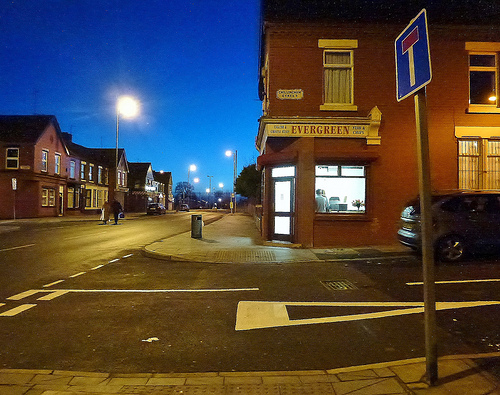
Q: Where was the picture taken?
A: It was taken at the street.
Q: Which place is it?
A: It is a street.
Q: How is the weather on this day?
A: It is clear.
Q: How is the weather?
A: It is clear.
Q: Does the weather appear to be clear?
A: Yes, it is clear.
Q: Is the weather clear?
A: Yes, it is clear.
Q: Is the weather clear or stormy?
A: It is clear.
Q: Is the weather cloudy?
A: No, it is clear.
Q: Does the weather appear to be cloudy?
A: No, it is clear.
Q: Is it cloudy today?
A: No, it is clear.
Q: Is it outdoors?
A: Yes, it is outdoors.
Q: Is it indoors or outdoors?
A: It is outdoors.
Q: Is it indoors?
A: No, it is outdoors.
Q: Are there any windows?
A: Yes, there is a window.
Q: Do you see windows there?
A: Yes, there is a window.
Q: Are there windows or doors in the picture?
A: Yes, there is a window.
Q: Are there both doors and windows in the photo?
A: Yes, there are both a window and a door.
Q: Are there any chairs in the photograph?
A: No, there are no chairs.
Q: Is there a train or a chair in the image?
A: No, there are no chairs or trains.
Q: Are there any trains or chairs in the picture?
A: No, there are no chairs or trains.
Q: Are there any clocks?
A: No, there are no clocks.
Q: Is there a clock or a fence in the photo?
A: No, there are no clocks or fences.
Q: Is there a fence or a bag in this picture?
A: No, there are no fences or bags.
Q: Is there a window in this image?
A: Yes, there is a window.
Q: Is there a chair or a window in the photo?
A: Yes, there is a window.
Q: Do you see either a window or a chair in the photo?
A: Yes, there is a window.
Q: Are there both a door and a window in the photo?
A: Yes, there are both a window and a door.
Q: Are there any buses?
A: No, there are no buses.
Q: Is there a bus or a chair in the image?
A: No, there are no buses or chairs.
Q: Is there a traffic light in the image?
A: No, there are no traffic lights.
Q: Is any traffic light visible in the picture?
A: No, there are no traffic lights.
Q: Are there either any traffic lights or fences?
A: No, there are no traffic lights or fences.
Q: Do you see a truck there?
A: No, there are no trucks.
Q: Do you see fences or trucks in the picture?
A: No, there are no trucks or fences.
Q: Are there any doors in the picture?
A: Yes, there is a door.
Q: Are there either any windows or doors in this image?
A: Yes, there is a door.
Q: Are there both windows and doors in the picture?
A: Yes, there are both a door and windows.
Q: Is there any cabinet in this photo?
A: No, there are no cabinets.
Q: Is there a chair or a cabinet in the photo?
A: No, there are no cabinets or chairs.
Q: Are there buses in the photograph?
A: No, there are no buses.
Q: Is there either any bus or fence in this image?
A: No, there are no buses or fences.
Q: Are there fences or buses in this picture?
A: No, there are no buses or fences.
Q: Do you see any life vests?
A: No, there are no life vests.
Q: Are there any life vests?
A: No, there are no life vests.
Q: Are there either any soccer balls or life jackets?
A: No, there are no life jackets or soccer balls.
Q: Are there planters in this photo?
A: No, there are no planters.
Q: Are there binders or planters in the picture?
A: No, there are no planters or binders.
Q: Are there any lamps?
A: Yes, there is a lamp.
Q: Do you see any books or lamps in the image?
A: Yes, there is a lamp.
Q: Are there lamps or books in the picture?
A: Yes, there is a lamp.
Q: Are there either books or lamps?
A: Yes, there is a lamp.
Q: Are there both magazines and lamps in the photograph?
A: No, there is a lamp but no magazines.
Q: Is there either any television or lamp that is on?
A: Yes, the lamp is on.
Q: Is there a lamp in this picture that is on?
A: Yes, there is a lamp that is on.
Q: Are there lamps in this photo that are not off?
A: Yes, there is a lamp that is on.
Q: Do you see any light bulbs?
A: No, there are no light bulbs.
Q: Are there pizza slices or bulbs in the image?
A: No, there are no bulbs or pizza slices.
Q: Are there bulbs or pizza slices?
A: No, there are no bulbs or pizza slices.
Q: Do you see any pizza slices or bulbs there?
A: No, there are no bulbs or pizza slices.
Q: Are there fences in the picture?
A: No, there are no fences.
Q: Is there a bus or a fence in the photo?
A: No, there are no fences or buses.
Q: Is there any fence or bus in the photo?
A: No, there are no fences or buses.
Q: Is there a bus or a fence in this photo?
A: No, there are no fences or buses.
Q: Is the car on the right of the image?
A: Yes, the car is on the right of the image.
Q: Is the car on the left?
A: No, the car is on the right of the image.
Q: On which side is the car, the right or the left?
A: The car is on the right of the image.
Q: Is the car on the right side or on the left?
A: The car is on the right of the image.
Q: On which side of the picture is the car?
A: The car is on the right of the image.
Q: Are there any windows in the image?
A: Yes, there is a window.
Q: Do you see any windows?
A: Yes, there is a window.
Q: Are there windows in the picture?
A: Yes, there is a window.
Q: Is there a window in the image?
A: Yes, there is a window.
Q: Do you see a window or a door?
A: Yes, there is a window.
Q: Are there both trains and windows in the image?
A: No, there is a window but no trains.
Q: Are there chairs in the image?
A: No, there are no chairs.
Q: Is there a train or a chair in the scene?
A: No, there are no chairs or trains.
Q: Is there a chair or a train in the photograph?
A: No, there are no chairs or trains.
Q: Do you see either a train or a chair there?
A: No, there are no chairs or trains.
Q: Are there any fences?
A: No, there are no fences.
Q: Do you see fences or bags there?
A: No, there are no fences or bags.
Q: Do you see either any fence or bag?
A: No, there are no fences or bags.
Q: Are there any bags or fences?
A: No, there are no fences or bags.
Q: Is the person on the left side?
A: Yes, the person is on the left of the image.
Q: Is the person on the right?
A: No, the person is on the left of the image.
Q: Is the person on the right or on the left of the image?
A: The person is on the left of the image.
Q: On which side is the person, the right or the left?
A: The person is on the left of the image.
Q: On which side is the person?
A: The person is on the left of the image.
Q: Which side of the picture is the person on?
A: The person is on the left of the image.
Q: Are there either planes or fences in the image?
A: No, there are no fences or planes.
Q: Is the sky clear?
A: Yes, the sky is clear.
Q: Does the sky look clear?
A: Yes, the sky is clear.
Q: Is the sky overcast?
A: No, the sky is clear.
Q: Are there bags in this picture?
A: No, there are no bags.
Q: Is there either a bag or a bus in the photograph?
A: No, there are no bags or buses.